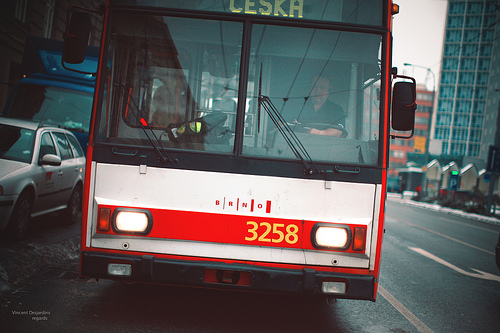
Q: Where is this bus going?
A: To the next stop.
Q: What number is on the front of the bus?
A: 3258.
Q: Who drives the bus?
A: The bus driver.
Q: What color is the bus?
A: Red and white.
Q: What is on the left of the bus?
A: A car.